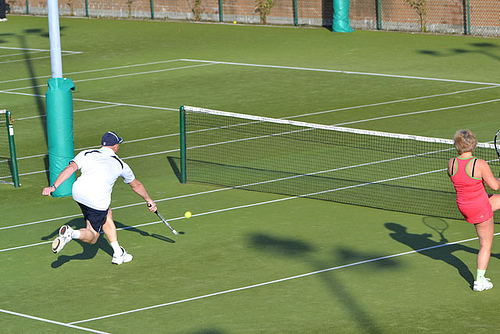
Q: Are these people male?
A: No, they are both male and female.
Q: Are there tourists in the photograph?
A: No, there are no tourists.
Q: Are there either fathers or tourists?
A: No, there are no tourists or fathers.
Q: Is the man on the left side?
A: Yes, the man is on the left of the image.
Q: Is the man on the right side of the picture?
A: No, the man is on the left of the image.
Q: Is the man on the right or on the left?
A: The man is on the left of the image.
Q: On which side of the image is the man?
A: The man is on the left of the image.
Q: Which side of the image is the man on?
A: The man is on the left of the image.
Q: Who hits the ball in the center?
A: The man hits the ball.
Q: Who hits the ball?
A: The man hits the ball.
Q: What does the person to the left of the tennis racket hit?
A: The man hits the ball.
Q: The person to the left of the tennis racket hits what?
A: The man hits the ball.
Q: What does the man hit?
A: The man hits the ball.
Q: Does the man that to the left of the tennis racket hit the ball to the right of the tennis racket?
A: Yes, the man hits the ball.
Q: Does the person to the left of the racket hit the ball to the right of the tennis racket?
A: Yes, the man hits the ball.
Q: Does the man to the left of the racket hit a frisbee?
A: No, the man hits the ball.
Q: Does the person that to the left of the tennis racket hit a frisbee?
A: No, the man hits the ball.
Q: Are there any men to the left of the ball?
A: Yes, there is a man to the left of the ball.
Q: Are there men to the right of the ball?
A: No, the man is to the left of the ball.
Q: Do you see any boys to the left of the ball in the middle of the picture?
A: No, there is a man to the left of the ball.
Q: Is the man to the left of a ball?
A: Yes, the man is to the left of a ball.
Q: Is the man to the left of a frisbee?
A: No, the man is to the left of a ball.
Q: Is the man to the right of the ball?
A: No, the man is to the left of the ball.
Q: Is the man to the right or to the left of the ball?
A: The man is to the left of the ball.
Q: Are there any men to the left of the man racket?
A: Yes, there is a man to the left of the racket.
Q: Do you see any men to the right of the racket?
A: No, the man is to the left of the racket.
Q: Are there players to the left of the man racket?
A: No, there is a man to the left of the racket.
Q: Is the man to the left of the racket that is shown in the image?
A: Yes, the man is to the left of the racket.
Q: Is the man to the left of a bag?
A: No, the man is to the left of the racket.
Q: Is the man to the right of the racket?
A: No, the man is to the left of the racket.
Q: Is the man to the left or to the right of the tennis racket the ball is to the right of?
A: The man is to the left of the racket.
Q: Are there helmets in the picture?
A: No, there are no helmets.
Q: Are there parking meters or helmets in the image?
A: No, there are no helmets or parking meters.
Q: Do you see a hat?
A: Yes, there is a hat.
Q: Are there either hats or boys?
A: Yes, there is a hat.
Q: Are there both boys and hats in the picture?
A: No, there is a hat but no boys.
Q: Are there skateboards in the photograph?
A: No, there are no skateboards.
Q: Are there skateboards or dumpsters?
A: No, there are no skateboards or dumpsters.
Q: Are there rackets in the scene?
A: Yes, there is a racket.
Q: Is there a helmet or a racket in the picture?
A: Yes, there is a racket.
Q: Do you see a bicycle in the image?
A: No, there are no bicycles.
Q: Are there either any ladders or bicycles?
A: No, there are no bicycles or ladders.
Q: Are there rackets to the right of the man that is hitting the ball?
A: Yes, there is a racket to the right of the man.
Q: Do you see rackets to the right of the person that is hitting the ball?
A: Yes, there is a racket to the right of the man.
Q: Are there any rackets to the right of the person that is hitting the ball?
A: Yes, there is a racket to the right of the man.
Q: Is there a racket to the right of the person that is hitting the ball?
A: Yes, there is a racket to the right of the man.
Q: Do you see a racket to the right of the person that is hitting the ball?
A: Yes, there is a racket to the right of the man.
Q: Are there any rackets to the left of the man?
A: No, the racket is to the right of the man.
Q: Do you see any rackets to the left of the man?
A: No, the racket is to the right of the man.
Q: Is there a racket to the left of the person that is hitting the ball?
A: No, the racket is to the right of the man.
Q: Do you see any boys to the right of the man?
A: No, there is a racket to the right of the man.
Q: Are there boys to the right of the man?
A: No, there is a racket to the right of the man.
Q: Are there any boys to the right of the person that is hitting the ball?
A: No, there is a racket to the right of the man.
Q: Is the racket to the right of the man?
A: Yes, the racket is to the right of the man.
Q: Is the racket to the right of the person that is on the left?
A: Yes, the racket is to the right of the man.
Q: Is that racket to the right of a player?
A: No, the racket is to the right of the man.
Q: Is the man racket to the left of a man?
A: No, the tennis racket is to the right of a man.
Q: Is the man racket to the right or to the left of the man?
A: The tennis racket is to the right of the man.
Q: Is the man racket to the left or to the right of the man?
A: The tennis racket is to the right of the man.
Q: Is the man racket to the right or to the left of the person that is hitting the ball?
A: The tennis racket is to the right of the man.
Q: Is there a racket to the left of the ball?
A: Yes, there is a racket to the left of the ball.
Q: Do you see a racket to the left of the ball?
A: Yes, there is a racket to the left of the ball.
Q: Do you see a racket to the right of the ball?
A: No, the racket is to the left of the ball.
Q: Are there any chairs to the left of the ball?
A: No, there is a racket to the left of the ball.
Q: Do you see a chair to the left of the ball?
A: No, there is a racket to the left of the ball.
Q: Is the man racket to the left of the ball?
A: Yes, the racket is to the left of the ball.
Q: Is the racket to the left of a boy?
A: No, the racket is to the left of the ball.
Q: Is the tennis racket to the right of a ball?
A: No, the tennis racket is to the left of a ball.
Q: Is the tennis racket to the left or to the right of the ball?
A: The tennis racket is to the left of the ball.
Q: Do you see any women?
A: Yes, there is a woman.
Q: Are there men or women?
A: Yes, there is a woman.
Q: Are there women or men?
A: Yes, there is a woman.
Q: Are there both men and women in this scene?
A: Yes, there are both a woman and a man.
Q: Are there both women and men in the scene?
A: Yes, there are both a woman and a man.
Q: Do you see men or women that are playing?
A: Yes, the woman is playing.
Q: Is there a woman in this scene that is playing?
A: Yes, there is a woman that is playing.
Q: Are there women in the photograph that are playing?
A: Yes, there is a woman that is playing.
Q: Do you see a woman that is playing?
A: Yes, there is a woman that is playing.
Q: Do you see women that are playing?
A: Yes, there is a woman that is playing.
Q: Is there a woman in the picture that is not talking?
A: Yes, there is a woman that is playing.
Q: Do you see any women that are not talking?
A: Yes, there is a woman that is playing .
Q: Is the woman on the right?
A: Yes, the woman is on the right of the image.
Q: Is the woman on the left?
A: No, the woman is on the right of the image.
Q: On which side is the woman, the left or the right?
A: The woman is on the right of the image.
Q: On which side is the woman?
A: The woman is on the right of the image.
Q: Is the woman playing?
A: Yes, the woman is playing.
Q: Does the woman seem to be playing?
A: Yes, the woman is playing.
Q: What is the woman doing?
A: The woman is playing.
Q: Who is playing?
A: The woman is playing.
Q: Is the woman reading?
A: No, the woman is playing.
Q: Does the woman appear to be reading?
A: No, the woman is playing.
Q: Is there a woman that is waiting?
A: No, there is a woman but she is playing.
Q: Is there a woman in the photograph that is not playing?
A: No, there is a woman but she is playing.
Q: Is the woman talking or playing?
A: The woman is playing.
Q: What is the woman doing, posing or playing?
A: The woman is playing.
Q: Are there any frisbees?
A: No, there are no frisbees.